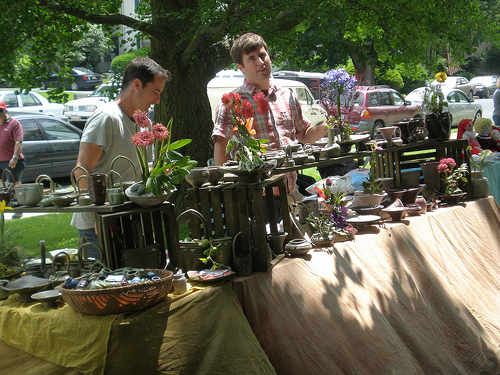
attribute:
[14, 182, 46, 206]
gray vase — small, grey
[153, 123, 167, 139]
flower — pink, small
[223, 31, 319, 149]
shirt — red, plaid, black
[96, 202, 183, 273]
box — wood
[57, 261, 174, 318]
basket — embroidered, small, wooden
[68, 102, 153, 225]
shirt — gray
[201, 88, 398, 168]
flowers — pink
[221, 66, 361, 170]
flowers — red, purple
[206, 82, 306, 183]
shirt — plaid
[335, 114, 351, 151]
stem — single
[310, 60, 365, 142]
flowers — purple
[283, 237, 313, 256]
vase — small, brown, ceramic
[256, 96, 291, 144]
shirt — dress shirt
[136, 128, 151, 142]
flower — small, pink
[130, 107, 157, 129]
flower top — small, pink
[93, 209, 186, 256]
drawer — brown, wooden